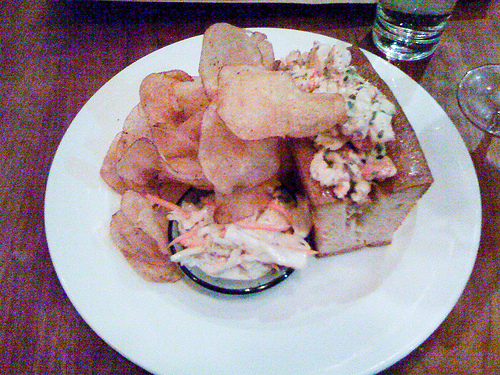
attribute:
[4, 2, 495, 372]
table — wood, brown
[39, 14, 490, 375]
plate — white, round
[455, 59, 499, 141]
glass — round, clear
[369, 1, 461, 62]
cup — clear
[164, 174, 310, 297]
dish — small, tiny, black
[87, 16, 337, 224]
chips — kettle cooked, light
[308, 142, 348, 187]
shrimp — pink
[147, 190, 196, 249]
carrot — orange